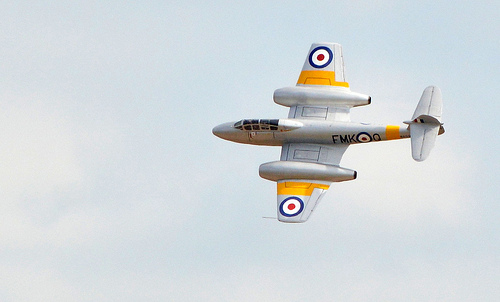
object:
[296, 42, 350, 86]
wing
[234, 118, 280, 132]
plane window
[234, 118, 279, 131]
window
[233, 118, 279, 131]
glass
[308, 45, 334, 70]
circle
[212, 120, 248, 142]
nose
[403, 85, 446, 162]
tail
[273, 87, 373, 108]
engine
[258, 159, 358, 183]
engine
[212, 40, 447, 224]
plane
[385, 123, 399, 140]
circle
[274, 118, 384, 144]
middle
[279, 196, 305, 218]
circle